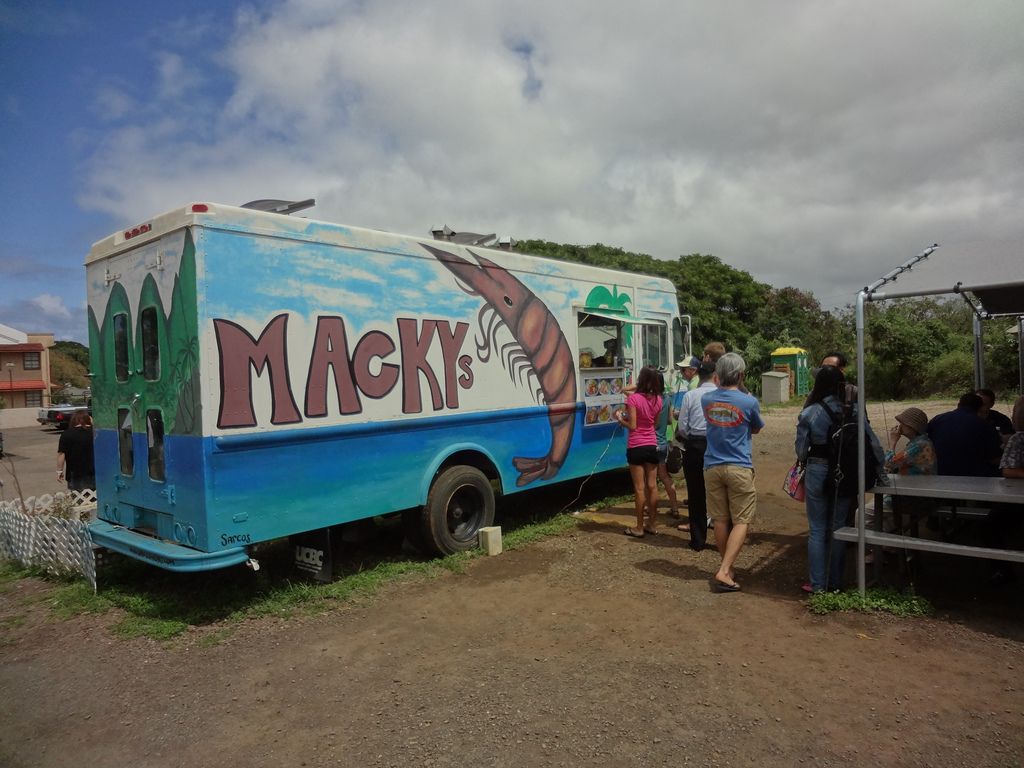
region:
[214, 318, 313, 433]
brown letter on truck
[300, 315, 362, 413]
brown letter on truck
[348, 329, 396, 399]
brown letter on truck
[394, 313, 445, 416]
brown letter on truck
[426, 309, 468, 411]
brown letter on truck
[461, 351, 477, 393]
brown letter on truck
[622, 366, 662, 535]
person waiting at truck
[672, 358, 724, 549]
person waiting at truck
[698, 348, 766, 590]
person waiting at truck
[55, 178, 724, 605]
THIS IS A FOOD TRUCK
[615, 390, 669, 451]
THE GIRL IS WEARING A PINK T-SHIRT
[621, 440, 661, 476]
THE GIRL IS WEARING BLACK SHORTS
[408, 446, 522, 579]
THIS IS A TIRE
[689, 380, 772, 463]
THE BOY IS WEARING A BLUE SHIRT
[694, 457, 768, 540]
THE BOY IS WEARING BROWN SHORTS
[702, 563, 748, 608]
THE BOY IS WEARING FLIP FLOPS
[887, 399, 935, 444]
THE WOMAN IS WEARING A HAT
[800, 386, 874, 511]
THE WOMAN IS WEARING A BACKPACK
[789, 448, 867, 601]
THE WOMAN IS WEARING JEANS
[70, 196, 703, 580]
blue and white truck parked in patch of grass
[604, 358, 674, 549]
girl in pink shirt standing outside of truck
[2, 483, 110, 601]
short white lattice fence at bottom of truck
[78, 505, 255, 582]
bumper on back of truck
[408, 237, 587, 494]
picture of red fish on front of truck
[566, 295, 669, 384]
open side window on side of truck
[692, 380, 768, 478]
blue short sleeve t-shirt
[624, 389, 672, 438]
a young girl wearing a pink shirt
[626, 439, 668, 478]
a young girl wearing black short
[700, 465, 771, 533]
a woman wearing brown shorts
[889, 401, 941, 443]
a woman wearing a hat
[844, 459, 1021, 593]
a picnic table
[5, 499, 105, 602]
a short white fence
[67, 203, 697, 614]
a van with paintings on it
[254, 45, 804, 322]
the sky is mostly cloudy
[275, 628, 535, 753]
the ground is brown and gray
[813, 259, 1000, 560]
this is a shelter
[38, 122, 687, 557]
blue food truck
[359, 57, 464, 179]
white clouds in blue sky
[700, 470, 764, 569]
the mans legs below torso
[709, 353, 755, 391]
the mans head above shoulders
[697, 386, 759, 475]
the mans shirt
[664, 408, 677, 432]
the mans hand at end of arm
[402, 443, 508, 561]
the vehicles rear tire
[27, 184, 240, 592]
the rear part of the vehicle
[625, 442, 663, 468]
Black shorts on a woman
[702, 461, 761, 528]
Shorts on a man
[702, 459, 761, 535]
Tan shorts on a man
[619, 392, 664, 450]
Shirt on a woman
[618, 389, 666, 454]
Pink shirt on a woman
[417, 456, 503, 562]
Black tire of a vehicle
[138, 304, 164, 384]
Window of a vehicle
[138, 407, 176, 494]
Window of a vehicle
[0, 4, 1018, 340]
white clouds in blue sky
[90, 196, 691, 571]
side of painted food truck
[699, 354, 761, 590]
person in blue shirt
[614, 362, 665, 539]
girl in pink top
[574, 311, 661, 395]
open food ordering window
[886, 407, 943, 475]
woman with hat on head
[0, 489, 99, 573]
short white decorative fence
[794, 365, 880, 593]
woman wearing pack on back